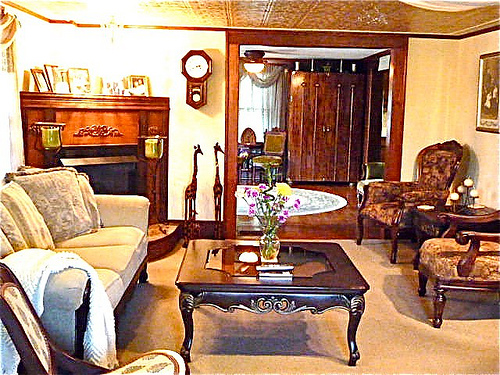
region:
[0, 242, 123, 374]
white afghan on back of chair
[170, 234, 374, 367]
elaborate wood and glass coffee table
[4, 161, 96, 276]
pillows on the back of a sofa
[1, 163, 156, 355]
cream colored sofa on dark wooden base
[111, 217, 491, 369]
tan carpeting with furniture on it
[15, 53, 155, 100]
framed family photos on the mantle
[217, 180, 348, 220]
oval white and bllue rug on dark wood floor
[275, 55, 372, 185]
dark wooden cabinets with folding doors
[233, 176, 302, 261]
purple and yellow flowers in a glass vase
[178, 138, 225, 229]
statue of giraffes on living room floor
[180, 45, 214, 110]
wooden wall clock with a pendulum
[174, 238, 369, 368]
wooden coffee table with a glass insert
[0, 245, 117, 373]
white throw blanket on the couch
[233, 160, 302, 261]
flower arrangement in a clear vase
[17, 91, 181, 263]
wooden decorative fire place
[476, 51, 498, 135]
framed painting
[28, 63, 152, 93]
cluster of framed photos on top of the fireplace mantel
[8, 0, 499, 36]
brass tin type ceiling tiles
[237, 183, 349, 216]
white circular area rug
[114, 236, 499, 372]
beige living room carpeting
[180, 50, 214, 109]
A small brown and white clock on the wall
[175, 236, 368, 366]
A dark cherry coffee table.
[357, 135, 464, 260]
A dark brown wooden framed chair in the corner.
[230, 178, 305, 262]
A vase holding yellow and purple flowers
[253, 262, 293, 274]
A long remote on the coffee table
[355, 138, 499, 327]
Two wood framed brown and tan arm chairs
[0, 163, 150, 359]
A wood framed tan couch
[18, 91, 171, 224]
A wooden fireplace.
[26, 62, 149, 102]
Lots of photos in frames on the mantle.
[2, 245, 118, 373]
A white throw on the side of a couch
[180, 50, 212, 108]
antique clock on the wall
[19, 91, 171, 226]
a dark colored wooden mantle over fire place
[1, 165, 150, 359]
an off white couch with big pillows on it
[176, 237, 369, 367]
a dark colored wooden coffee table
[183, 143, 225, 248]
decorative giraffe statues against wall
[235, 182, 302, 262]
flowers in a vase on coffee table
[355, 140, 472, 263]
a brown patterned arm chair against wall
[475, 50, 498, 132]
a framed picture on the wall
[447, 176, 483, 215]
round white candles on side table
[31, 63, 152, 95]
framed pictures on the mantle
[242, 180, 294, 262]
pink and yellow flowers in vase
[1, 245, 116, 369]
white throw blanket on couch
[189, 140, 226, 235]
brown giraffe statues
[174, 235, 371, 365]
wood coffee table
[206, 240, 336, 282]
glass on top of coffee table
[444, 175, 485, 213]
round yellow candles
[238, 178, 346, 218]
blue and white oblong shaped rug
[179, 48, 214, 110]
wooden wall clock with round face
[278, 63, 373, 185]
tall wooden brown door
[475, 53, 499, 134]
wall painting with people in it